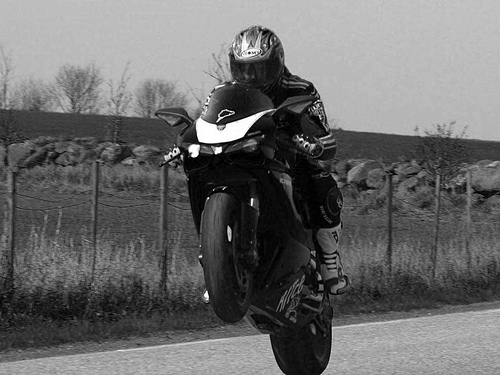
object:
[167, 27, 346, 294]
man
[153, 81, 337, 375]
motorcycle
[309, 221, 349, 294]
boots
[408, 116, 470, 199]
trees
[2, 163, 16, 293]
posts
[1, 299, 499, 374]
road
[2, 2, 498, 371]
photo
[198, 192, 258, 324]
tire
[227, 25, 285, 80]
helmet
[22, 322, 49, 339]
grass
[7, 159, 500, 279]
fence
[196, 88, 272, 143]
windsheild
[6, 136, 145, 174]
rock wall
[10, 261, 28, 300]
weeds